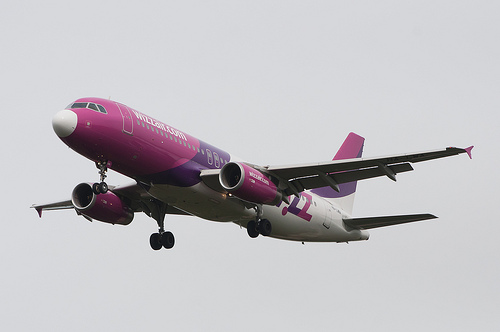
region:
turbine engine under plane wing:
[221, 161, 286, 207]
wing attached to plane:
[201, 146, 463, 193]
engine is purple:
[218, 161, 282, 208]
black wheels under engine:
[247, 218, 270, 235]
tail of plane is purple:
[308, 133, 364, 220]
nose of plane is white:
[52, 108, 77, 136]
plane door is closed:
[116, 101, 135, 135]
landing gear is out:
[91, 158, 108, 193]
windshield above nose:
[67, 102, 89, 108]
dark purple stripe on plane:
[146, 140, 232, 187]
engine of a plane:
[210, 159, 285, 215]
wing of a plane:
[262, 133, 480, 203]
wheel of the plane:
[143, 228, 183, 256]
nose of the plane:
[46, 108, 75, 136]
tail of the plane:
[302, 130, 374, 215]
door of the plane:
[114, 98, 136, 139]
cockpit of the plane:
[63, 95, 111, 117]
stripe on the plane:
[146, 136, 248, 191]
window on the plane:
[101, 124, 241, 152]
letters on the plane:
[128, 98, 190, 140]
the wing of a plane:
[274, 144, 476, 190]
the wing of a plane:
[31, 199, 72, 214]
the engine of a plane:
[72, 181, 137, 227]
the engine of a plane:
[217, 157, 287, 209]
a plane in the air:
[16, 94, 481, 254]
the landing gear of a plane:
[91, 165, 112, 197]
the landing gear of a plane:
[145, 215, 177, 251]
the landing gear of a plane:
[245, 206, 274, 240]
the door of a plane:
[116, 100, 137, 135]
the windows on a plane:
[148, 126, 188, 141]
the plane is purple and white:
[66, 96, 413, 296]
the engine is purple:
[213, 156, 294, 213]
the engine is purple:
[75, 193, 148, 228]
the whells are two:
[86, 172, 126, 205]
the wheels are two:
[144, 221, 189, 256]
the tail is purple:
[320, 139, 370, 210]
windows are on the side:
[138, 118, 230, 167]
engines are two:
[22, 96, 467, 261]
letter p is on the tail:
[283, 189, 325, 231]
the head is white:
[45, 111, 83, 134]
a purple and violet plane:
[53, 72, 403, 258]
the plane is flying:
[41, 53, 412, 307]